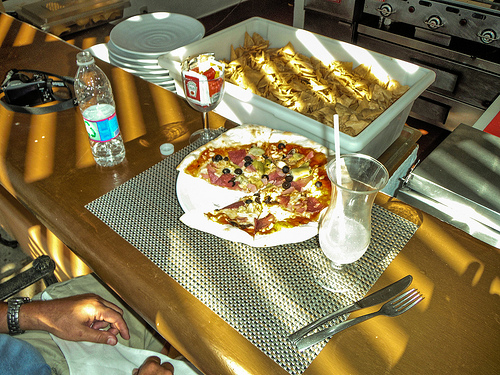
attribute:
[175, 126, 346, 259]
pizza — round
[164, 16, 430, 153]
box — white, plastic